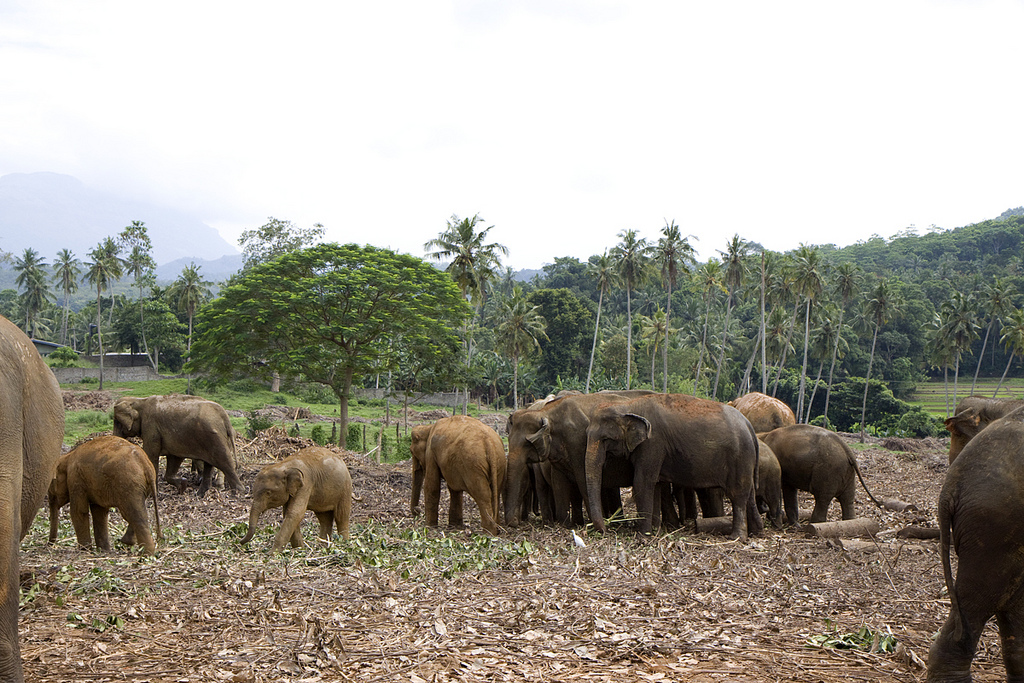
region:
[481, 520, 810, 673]
the dirt is very dry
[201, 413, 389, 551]
the elephant is smaller than the others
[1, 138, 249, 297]
mountains are in the background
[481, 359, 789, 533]
the elephants are brown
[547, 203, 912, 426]
the trees are in a row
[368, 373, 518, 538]
the elephant is reddish brown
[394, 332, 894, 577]
the elephants are in a huddle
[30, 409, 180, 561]
the elephants head is down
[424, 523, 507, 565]
grass is tall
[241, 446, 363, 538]
a small elephant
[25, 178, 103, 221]
a mountain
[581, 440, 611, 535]
the elephants trunk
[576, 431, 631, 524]
the trunk is brown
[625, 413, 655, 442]
the elephants ear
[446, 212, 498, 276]
a palm tree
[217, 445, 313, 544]
the head of a elephant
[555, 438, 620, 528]
the trunk of a elephant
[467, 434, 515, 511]
the tail of a elephant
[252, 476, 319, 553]
the front legs of a elephant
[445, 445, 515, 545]
the back legs of a elephant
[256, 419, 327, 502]
the ear of a elephant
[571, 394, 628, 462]
the eye of a elephant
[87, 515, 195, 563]
the feet of a elephant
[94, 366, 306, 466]
the body of a elephant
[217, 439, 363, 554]
elephant walking in the field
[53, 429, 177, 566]
elephant walking in the field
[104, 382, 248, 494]
elephant walking in the field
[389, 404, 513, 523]
elephant walking in the field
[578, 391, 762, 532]
elephant walking in the field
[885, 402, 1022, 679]
elephant walking in the field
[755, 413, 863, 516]
elephant walking in the field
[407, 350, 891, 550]
group of elephants in the field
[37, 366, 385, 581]
group of elephants in the field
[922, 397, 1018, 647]
group of elephants in the field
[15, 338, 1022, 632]
a herd of elephants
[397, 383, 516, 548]
a tan colored elephant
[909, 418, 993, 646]
a tail on a elephant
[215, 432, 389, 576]
a tiny baby elephant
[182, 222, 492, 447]
a large green tree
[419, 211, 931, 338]
the tops of palm trees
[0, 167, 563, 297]
mountians in the background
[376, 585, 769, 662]
the ground is covered in brown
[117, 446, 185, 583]
the back of a elephant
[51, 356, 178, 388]
the pond behind the trees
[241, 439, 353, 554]
the baby elephant is gray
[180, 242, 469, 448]
the tree is very bright green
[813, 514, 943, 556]
the logs under the elephants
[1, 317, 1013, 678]
elephants grazing in a field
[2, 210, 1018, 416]
trees near a herd of elephants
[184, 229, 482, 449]
a tree in a field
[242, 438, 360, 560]
a baby elephant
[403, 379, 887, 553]
several elephants hunched together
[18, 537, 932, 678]
dirt in a field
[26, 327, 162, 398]
a building in the back of the field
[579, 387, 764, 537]
large elephant in a field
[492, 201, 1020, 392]
a hill behind the herd of elephants